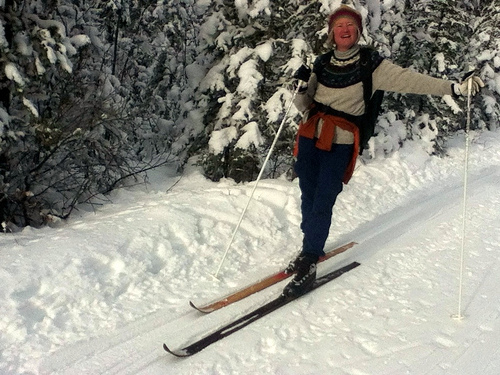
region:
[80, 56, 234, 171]
snow covered trees in the woods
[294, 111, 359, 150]
orange sweater around a waist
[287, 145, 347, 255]
blue pants on the woman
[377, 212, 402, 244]
ski tracks in the snow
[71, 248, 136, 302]
snow packed white snow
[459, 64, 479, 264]
a ski pole in the hand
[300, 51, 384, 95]
black scarf around womans neck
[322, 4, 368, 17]
red hat the woman is wearing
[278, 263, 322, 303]
black and white boots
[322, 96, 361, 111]
part of the tan shirt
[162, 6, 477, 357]
a woman getting ready to ski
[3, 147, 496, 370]
the snow on the ground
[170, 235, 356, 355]
the skis that are on the woman's feet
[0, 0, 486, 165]
the trees off to the side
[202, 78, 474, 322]
the poles the woman is holding onto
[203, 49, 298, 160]
the snow on the tree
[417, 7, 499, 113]
some more snow on the tree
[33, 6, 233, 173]
more snow covered trees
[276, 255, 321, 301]
the boots on the womans feet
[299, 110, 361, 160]
the jacket tied around the woman's waist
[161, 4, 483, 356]
woman skiing in snow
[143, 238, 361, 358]
skis on the woman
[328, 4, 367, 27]
hat on the woman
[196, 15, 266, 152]
snow piles on the trees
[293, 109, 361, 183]
orangish shirt tied around woman's waist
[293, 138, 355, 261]
dark pants on woman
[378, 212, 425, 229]
track from woman skiing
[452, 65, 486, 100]
glove on woman's hand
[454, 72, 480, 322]
pole with the ski wear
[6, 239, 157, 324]
snow pile to the side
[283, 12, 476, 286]
the skier is an elderly woman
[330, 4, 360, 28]
the lady is wearing a hat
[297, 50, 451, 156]
the lady is wearing a sweater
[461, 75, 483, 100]
the lady is wearing gloves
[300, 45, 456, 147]
the sweater is light grey in color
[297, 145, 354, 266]
the woman is wearing long pants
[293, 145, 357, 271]
the pants are black in color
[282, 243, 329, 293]
the woman is wearing boots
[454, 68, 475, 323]
the woman is holding ski poles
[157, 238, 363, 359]
the woman has ski poles on her boots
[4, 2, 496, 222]
tree branches covered in snow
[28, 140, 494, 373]
path between snow banks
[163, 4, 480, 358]
person leaning on ski poles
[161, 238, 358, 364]
two skis on boots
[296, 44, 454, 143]
gray sweater with design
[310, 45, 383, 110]
black straps on sweater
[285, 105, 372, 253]
sweater wrapped around waist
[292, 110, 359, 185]
tied arms of sweater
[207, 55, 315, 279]
white pole in hand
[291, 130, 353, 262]
blue pants on legs